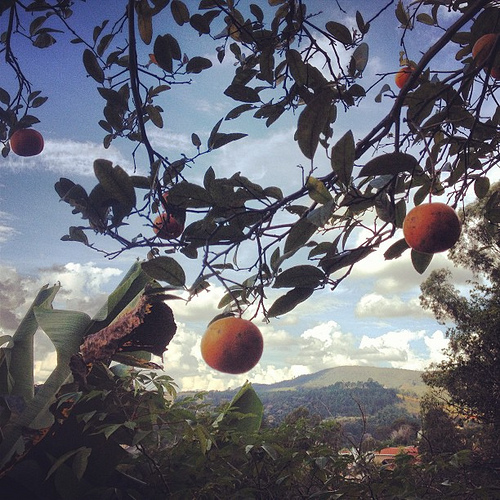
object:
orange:
[401, 201, 462, 254]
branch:
[429, 63, 477, 206]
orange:
[394, 66, 422, 92]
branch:
[398, 0, 426, 65]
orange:
[200, 316, 264, 375]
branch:
[249, 226, 280, 324]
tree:
[0, 1, 500, 375]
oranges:
[151, 212, 185, 241]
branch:
[123, 3, 180, 219]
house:
[373, 445, 424, 472]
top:
[325, 364, 402, 376]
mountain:
[266, 365, 450, 403]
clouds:
[53, 156, 87, 170]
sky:
[0, 0, 500, 393]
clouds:
[354, 292, 414, 323]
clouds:
[301, 320, 340, 340]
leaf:
[270, 264, 328, 290]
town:
[302, 441, 500, 500]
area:
[268, 364, 465, 403]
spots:
[237, 332, 242, 338]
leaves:
[329, 129, 356, 188]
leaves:
[92, 157, 137, 211]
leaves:
[295, 90, 330, 161]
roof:
[380, 445, 422, 469]